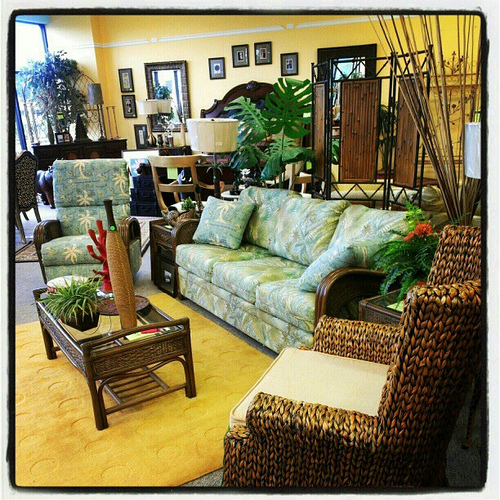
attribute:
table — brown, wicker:
[33, 282, 208, 434]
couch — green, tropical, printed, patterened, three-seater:
[174, 182, 410, 355]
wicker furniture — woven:
[217, 219, 484, 489]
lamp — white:
[137, 96, 165, 143]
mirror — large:
[146, 62, 190, 130]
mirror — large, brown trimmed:
[140, 60, 192, 136]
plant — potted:
[37, 277, 100, 331]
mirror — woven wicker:
[138, 41, 198, 142]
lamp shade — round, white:
[180, 114, 241, 156]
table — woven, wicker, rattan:
[15, 259, 250, 431]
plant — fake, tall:
[226, 78, 317, 191]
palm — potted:
[221, 74, 324, 201]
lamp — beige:
[183, 113, 242, 203]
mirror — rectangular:
[139, 60, 194, 125]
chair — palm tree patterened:
[33, 157, 140, 281]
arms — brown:
[33, 214, 152, 249]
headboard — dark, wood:
[197, 79, 316, 122]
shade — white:
[184, 117, 238, 154]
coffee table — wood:
[31, 287, 196, 429]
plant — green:
[379, 204, 437, 284]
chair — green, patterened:
[244, 168, 478, 465]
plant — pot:
[374, 231, 433, 291]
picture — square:
[227, 42, 251, 69]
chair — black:
[0, 141, 72, 213]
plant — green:
[38, 279, 98, 326]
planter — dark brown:
[61, 297, 101, 334]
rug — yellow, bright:
[14, 291, 273, 486]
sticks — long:
[374, 13, 482, 220]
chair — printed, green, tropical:
[44, 189, 94, 269]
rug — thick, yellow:
[160, 343, 291, 461]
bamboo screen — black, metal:
[308, 62, 448, 204]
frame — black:
[315, 57, 427, 69]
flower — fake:
[401, 218, 432, 248]